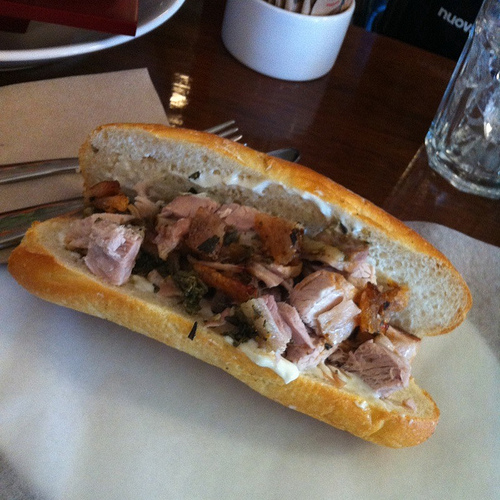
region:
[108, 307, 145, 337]
edge of a bread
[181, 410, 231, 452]
edge of a shade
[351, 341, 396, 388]
part of a cream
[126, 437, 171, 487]
part of a cloth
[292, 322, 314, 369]
edge of a cream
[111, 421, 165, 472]
part of a cloth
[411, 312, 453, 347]
edge of a bread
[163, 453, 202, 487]
part of a table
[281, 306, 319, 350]
edge of a cream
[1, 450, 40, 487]
edge of a cloth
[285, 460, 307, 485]
the napkin is white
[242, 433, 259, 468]
the napkin is white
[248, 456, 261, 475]
the napkin is white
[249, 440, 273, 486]
the napkin is white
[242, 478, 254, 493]
the napkin is white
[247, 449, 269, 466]
the napkin is white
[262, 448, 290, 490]
the napkin is white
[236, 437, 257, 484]
the napkin is white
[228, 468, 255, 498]
the napkin is white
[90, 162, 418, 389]
pork meat on roll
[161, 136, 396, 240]
mayonnaise on the bread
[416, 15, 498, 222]
clear mug on table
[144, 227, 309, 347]
spices on the meat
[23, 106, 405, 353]
golden brown sub roll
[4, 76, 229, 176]
brown napkin on table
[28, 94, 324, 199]
fork on brown napkin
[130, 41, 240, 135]
light reflected on table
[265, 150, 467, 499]
sandwich on white paper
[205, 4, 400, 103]
white dish of condiments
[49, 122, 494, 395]
The sandwich is full of meat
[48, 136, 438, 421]
The sub has white bread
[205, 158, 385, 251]
Mayonnaise is on the sandwich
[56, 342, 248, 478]
The plate is white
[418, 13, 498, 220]
Glass has ice in it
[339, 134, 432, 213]
The table is dark brown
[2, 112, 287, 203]
The silverware is laying on the table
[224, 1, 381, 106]
A cup is holding sugar packets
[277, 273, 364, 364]
There are chunks of ham on the sandwich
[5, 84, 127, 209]
The napkin lays under the silverware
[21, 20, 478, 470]
sandwich on a dark table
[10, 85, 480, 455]
Italian bread split open horizontally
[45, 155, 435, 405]
chunks of meat between bread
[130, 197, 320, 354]
green herbs sprinkled on sandwich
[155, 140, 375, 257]
creamy white condiment on edge of bread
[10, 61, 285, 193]
brown napkin behind sandwich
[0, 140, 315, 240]
fork and knife behind white place mat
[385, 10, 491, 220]
clear glass with water reflected on table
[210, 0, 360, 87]
white ceramic container with packets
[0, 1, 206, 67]
rim of white plate with dark fabric on top